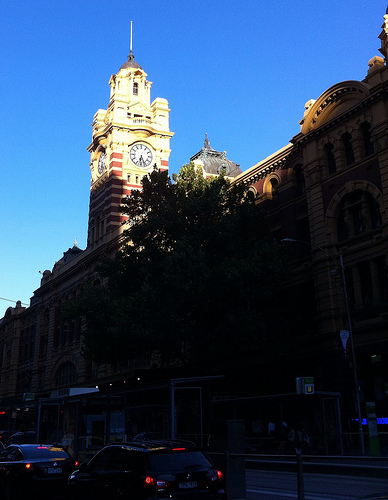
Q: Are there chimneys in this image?
A: No, there are no chimneys.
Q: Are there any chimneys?
A: No, there are no chimneys.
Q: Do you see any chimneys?
A: No, there are no chimneys.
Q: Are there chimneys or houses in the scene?
A: No, there are no chimneys or houses.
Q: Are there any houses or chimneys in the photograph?
A: No, there are no chimneys or houses.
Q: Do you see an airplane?
A: No, there are no airplanes.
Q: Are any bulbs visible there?
A: No, there are no bulbs.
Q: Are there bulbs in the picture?
A: No, there are no bulbs.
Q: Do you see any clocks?
A: Yes, there is a clock.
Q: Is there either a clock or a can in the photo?
A: Yes, there is a clock.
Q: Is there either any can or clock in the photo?
A: Yes, there is a clock.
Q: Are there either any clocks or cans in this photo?
A: Yes, there is a clock.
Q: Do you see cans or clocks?
A: Yes, there is a clock.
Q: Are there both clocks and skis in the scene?
A: No, there is a clock but no skis.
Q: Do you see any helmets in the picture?
A: No, there are no helmets.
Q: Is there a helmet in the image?
A: No, there are no helmets.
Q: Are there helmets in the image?
A: No, there are no helmets.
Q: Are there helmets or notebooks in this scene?
A: No, there are no helmets or notebooks.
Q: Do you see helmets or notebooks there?
A: No, there are no helmets or notebooks.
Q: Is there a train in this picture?
A: No, there are no trains.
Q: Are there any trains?
A: No, there are no trains.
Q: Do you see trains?
A: No, there are no trains.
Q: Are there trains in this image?
A: No, there are no trains.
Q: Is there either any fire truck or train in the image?
A: No, there are no trains or fire trucks.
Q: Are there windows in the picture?
A: Yes, there is a window.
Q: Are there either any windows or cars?
A: Yes, there is a window.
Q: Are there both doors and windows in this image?
A: No, there is a window but no doors.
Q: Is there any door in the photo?
A: No, there are no doors.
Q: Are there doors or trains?
A: No, there are no doors or trains.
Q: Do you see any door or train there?
A: No, there are no doors or trains.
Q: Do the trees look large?
A: Yes, the trees are large.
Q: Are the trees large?
A: Yes, the trees are large.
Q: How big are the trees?
A: The trees are large.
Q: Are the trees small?
A: No, the trees are large.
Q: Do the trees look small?
A: No, the trees are large.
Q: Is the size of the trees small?
A: No, the trees are large.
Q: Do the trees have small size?
A: No, the trees are large.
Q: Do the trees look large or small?
A: The trees are large.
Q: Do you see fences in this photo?
A: Yes, there is a fence.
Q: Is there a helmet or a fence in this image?
A: Yes, there is a fence.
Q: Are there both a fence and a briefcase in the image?
A: No, there is a fence but no briefcases.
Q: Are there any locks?
A: No, there are no locks.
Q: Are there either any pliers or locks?
A: No, there are no locks or pliers.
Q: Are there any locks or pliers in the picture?
A: No, there are no locks or pliers.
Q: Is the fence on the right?
A: Yes, the fence is on the right of the image.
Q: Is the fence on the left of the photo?
A: No, the fence is on the right of the image.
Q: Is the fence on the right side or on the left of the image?
A: The fence is on the right of the image.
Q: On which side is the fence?
A: The fence is on the right of the image.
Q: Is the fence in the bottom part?
A: Yes, the fence is in the bottom of the image.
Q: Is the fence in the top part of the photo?
A: No, the fence is in the bottom of the image.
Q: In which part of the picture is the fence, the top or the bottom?
A: The fence is in the bottom of the image.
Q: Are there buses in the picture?
A: No, there are no buses.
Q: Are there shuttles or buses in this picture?
A: No, there are no buses or shuttles.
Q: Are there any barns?
A: No, there are no barns.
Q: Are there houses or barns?
A: No, there are no barns or houses.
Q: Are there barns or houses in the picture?
A: No, there are no barns or houses.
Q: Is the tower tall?
A: Yes, the tower is tall.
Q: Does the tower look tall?
A: Yes, the tower is tall.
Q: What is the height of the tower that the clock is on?
A: The tower is tall.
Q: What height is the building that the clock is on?
A: The tower is tall.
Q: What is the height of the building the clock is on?
A: The tower is tall.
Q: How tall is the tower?
A: The tower is tall.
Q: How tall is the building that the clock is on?
A: The tower is tall.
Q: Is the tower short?
A: No, the tower is tall.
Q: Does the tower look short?
A: No, the tower is tall.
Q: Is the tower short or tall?
A: The tower is tall.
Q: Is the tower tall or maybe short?
A: The tower is tall.